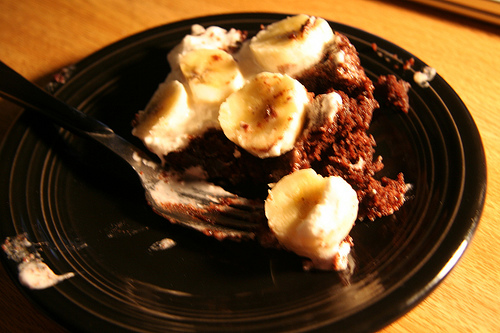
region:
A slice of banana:
[264, 164, 350, 254]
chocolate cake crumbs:
[307, 93, 382, 175]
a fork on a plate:
[7, 56, 260, 243]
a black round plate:
[9, 7, 492, 325]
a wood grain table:
[0, 1, 497, 60]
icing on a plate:
[14, 247, 76, 302]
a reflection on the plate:
[277, 273, 400, 318]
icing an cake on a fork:
[3, 71, 260, 242]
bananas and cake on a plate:
[1, 1, 485, 321]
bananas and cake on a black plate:
[12, 5, 499, 329]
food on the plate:
[113, 13, 444, 260]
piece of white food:
[227, 78, 304, 147]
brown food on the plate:
[323, 113, 388, 185]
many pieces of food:
[173, 35, 418, 254]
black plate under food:
[379, 109, 475, 176]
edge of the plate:
[422, 83, 492, 170]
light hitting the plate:
[324, 260, 402, 323]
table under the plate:
[431, 269, 494, 327]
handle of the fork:
[10, 50, 161, 183]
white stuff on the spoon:
[146, 163, 230, 225]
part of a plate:
[456, 233, 472, 245]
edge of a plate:
[355, 294, 363, 306]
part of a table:
[439, 283, 449, 313]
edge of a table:
[463, 279, 475, 308]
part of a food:
[343, 208, 370, 211]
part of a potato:
[301, 202, 315, 224]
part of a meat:
[353, 170, 361, 204]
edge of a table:
[416, 303, 430, 320]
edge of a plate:
[242, 298, 247, 304]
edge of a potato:
[236, 130, 251, 156]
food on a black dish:
[12, 11, 493, 326]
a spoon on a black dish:
[0, 58, 279, 248]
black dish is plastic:
[6, 5, 495, 327]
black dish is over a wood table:
[12, 8, 497, 319]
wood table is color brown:
[0, 1, 499, 323]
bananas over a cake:
[118, 12, 424, 277]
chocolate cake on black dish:
[305, 45, 418, 202]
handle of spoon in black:
[0, 60, 115, 148]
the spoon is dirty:
[2, 57, 268, 244]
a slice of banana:
[254, 159, 360, 259]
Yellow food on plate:
[260, 163, 360, 261]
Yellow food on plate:
[222, 75, 291, 135]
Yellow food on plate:
[243, 7, 333, 63]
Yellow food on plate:
[131, 77, 203, 159]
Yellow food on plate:
[167, 40, 229, 102]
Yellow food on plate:
[310, 85, 386, 200]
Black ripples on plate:
[159, 286, 211, 331]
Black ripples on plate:
[220, 292, 259, 329]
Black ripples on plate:
[276, 282, 311, 314]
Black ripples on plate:
[329, 262, 384, 304]